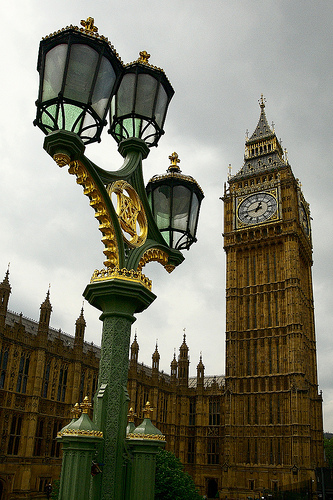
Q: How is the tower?
A: Tall.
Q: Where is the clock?
A: On the tower.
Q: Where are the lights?
A: In front of the tower.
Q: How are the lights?
A: Off.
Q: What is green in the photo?
A: The lights.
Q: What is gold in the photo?
A: Filigree on the light.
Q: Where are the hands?
A: On the clock.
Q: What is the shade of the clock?
A: White.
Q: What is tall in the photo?
A: The tower with the clock.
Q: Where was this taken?
A: London.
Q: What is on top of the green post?
A: 3 lamps.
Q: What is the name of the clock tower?
A: Big Ben.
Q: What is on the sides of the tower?
A: Clocks.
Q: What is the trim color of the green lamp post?
A: Gold.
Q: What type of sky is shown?
A: Cloudy.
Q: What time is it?
A: 12:45.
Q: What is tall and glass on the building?
A: The windows.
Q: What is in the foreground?
A: A lamp post.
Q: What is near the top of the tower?
A: A clock.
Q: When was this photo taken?
A: During the day.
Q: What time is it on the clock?
A: 12:45.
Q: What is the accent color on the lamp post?
A: Gold.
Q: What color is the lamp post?
A: Green.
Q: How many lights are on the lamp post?
A: Three.